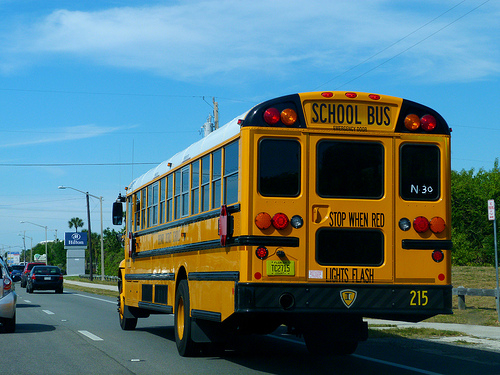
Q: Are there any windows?
A: Yes, there are windows.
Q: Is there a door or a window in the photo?
A: Yes, there are windows.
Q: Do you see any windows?
A: Yes, there are windows.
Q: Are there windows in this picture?
A: Yes, there are windows.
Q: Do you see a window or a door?
A: Yes, there are windows.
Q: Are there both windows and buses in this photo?
A: Yes, there are both windows and a bus.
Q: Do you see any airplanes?
A: No, there are no airplanes.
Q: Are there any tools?
A: No, there are no tools.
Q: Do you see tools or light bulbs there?
A: No, there are no tools or light bulbs.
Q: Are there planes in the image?
A: No, there are no planes.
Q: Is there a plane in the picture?
A: No, there are no airplanes.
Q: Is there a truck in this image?
A: No, there are no trucks.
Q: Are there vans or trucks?
A: No, there are no trucks or vans.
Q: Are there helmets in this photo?
A: No, there are no helmets.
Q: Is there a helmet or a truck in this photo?
A: No, there are no helmets or trucks.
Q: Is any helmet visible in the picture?
A: No, there are no helmets.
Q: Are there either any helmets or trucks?
A: No, there are no helmets or trucks.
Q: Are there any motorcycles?
A: No, there are no motorcycles.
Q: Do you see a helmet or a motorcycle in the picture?
A: No, there are no motorcycles or helmets.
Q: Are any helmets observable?
A: No, there are no helmets.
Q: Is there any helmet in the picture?
A: No, there are no helmets.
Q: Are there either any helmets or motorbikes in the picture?
A: No, there are no helmets or motorbikes.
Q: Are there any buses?
A: Yes, there is a bus.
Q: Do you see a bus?
A: Yes, there is a bus.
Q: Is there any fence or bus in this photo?
A: Yes, there is a bus.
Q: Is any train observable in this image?
A: No, there are no trains.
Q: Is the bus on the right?
A: Yes, the bus is on the right of the image.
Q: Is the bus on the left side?
A: No, the bus is on the right of the image.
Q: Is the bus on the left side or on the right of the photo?
A: The bus is on the right of the image.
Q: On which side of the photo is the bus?
A: The bus is on the right of the image.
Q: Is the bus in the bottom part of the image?
A: Yes, the bus is in the bottom of the image.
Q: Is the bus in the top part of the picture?
A: No, the bus is in the bottom of the image.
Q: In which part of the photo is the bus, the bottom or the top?
A: The bus is in the bottom of the image.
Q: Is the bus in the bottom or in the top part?
A: The bus is in the bottom of the image.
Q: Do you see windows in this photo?
A: Yes, there is a window.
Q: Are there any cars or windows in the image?
A: Yes, there is a window.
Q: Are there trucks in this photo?
A: No, there are no trucks.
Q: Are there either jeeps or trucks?
A: No, there are no trucks or jeeps.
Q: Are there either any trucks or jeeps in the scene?
A: No, there are no trucks or jeeps.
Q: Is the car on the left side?
A: Yes, the car is on the left of the image.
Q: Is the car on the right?
A: No, the car is on the left of the image.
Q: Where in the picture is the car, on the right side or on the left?
A: The car is on the left of the image.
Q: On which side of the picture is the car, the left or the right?
A: The car is on the left of the image.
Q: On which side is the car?
A: The car is on the left of the image.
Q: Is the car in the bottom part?
A: Yes, the car is in the bottom of the image.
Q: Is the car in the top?
A: No, the car is in the bottom of the image.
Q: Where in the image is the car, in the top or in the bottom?
A: The car is in the bottom of the image.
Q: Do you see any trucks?
A: No, there are no trucks.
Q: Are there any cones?
A: No, there are no cones.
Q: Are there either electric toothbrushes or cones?
A: No, there are no cones or electric toothbrushes.